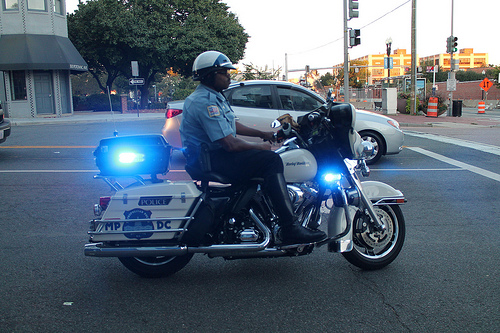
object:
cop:
[179, 50, 328, 245]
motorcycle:
[83, 88, 409, 278]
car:
[162, 80, 406, 165]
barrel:
[427, 97, 438, 117]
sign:
[479, 77, 494, 91]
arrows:
[483, 81, 489, 88]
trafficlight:
[446, 35, 459, 54]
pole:
[449, 91, 453, 116]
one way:
[128, 78, 145, 86]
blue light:
[110, 144, 145, 168]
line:
[402, 128, 499, 156]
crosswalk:
[402, 115, 500, 182]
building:
[333, 48, 421, 86]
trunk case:
[91, 133, 173, 176]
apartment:
[0, 0, 89, 119]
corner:
[348, 43, 435, 125]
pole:
[409, 0, 416, 115]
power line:
[353, 0, 411, 34]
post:
[135, 85, 139, 117]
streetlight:
[385, 37, 393, 56]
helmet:
[191, 50, 237, 92]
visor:
[222, 64, 236, 70]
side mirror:
[270, 119, 282, 129]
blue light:
[323, 173, 341, 184]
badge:
[207, 105, 220, 117]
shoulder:
[189, 90, 220, 118]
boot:
[264, 173, 328, 244]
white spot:
[63, 301, 74, 306]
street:
[0, 126, 499, 333]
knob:
[113, 129, 118, 136]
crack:
[362, 265, 412, 332]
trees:
[66, 2, 252, 110]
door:
[33, 70, 56, 115]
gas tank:
[279, 148, 318, 183]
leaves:
[65, 0, 251, 79]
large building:
[419, 48, 488, 72]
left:
[0, 0, 97, 332]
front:
[357, 109, 405, 165]